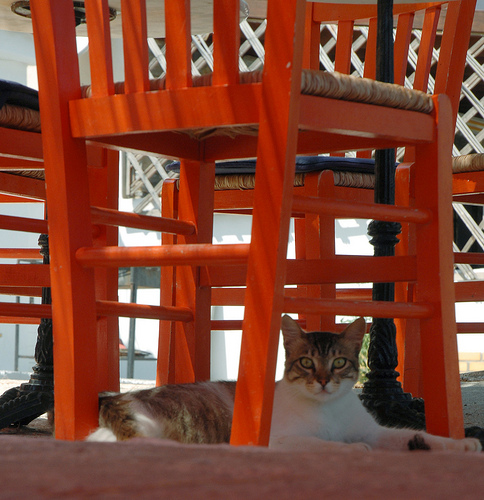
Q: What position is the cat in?
A: Laying.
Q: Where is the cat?
A: Under a chair.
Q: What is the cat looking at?
A: Camera.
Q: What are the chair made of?
A: Wood.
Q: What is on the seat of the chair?
A: Padding.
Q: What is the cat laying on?
A: Carpet.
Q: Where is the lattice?
A: Background.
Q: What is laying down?
A: The cat is.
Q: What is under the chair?
A: One cat is under.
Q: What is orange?
A: The chair.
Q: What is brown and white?
A: The cat is that color.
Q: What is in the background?
A: The fence is.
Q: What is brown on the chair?
A: The seat is brown.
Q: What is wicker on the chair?
A: The seat is.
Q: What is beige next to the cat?
A: The ground is beige.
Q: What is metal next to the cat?
A: The pole is metal.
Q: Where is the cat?
A: Under a chair.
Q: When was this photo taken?
A: Daytime.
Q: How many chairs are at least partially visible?
A: Five.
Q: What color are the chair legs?
A: Orange.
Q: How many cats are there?
A: One.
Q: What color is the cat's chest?
A: White.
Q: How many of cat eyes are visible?
A: Two.